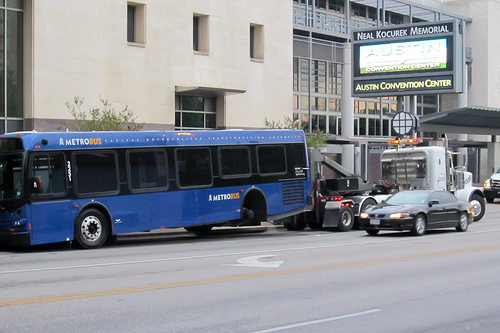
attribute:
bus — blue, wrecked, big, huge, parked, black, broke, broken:
[4, 124, 319, 254]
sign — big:
[341, 20, 466, 119]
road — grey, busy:
[5, 191, 494, 332]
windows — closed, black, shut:
[67, 146, 280, 196]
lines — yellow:
[6, 241, 485, 331]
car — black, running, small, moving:
[359, 183, 472, 239]